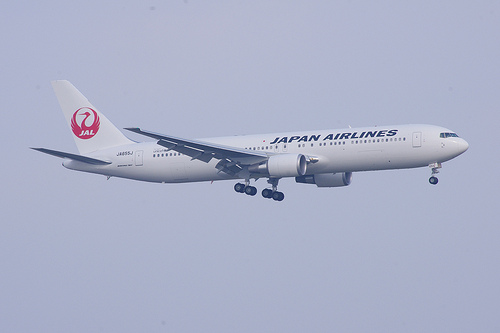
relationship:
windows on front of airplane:
[436, 129, 467, 142] [28, 78, 470, 202]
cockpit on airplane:
[432, 123, 468, 164] [28, 78, 470, 202]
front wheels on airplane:
[427, 174, 440, 186] [27, 73, 465, 207]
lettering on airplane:
[268, 133, 277, 145] [28, 78, 470, 202]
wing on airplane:
[125, 122, 322, 180] [28, 78, 470, 202]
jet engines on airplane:
[295, 168, 353, 188] [28, 78, 470, 202]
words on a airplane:
[268, 129, 407, 142] [28, 78, 470, 202]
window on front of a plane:
[438, 131, 449, 143] [23, 65, 478, 200]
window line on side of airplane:
[149, 133, 408, 160] [28, 78, 470, 202]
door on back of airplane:
[134, 145, 143, 169] [28, 78, 470, 202]